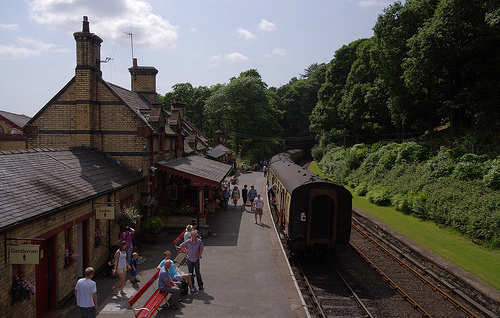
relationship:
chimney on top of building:
[66, 20, 128, 88] [46, 56, 227, 180]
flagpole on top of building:
[128, 30, 139, 67] [0, 15, 235, 317]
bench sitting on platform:
[127, 257, 184, 314] [73, 217, 216, 304]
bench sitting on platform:
[167, 225, 185, 251] [73, 217, 216, 304]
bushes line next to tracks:
[313, 141, 498, 240] [284, 208, 499, 316]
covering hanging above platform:
[165, 157, 235, 185] [159, 178, 213, 225]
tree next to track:
[201, 66, 289, 171] [355, 209, 481, 305]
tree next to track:
[155, 81, 226, 132] [355, 209, 481, 305]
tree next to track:
[270, 74, 320, 144] [355, 209, 481, 305]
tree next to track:
[308, 37, 372, 144] [355, 209, 481, 305]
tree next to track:
[397, 0, 497, 135] [355, 209, 481, 305]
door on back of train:
[310, 192, 336, 237] [268, 140, 376, 266]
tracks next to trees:
[359, 215, 462, 315] [295, 24, 499, 224]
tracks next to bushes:
[359, 215, 462, 315] [362, 152, 481, 210]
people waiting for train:
[228, 182, 269, 223] [273, 147, 355, 252]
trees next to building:
[218, 7, 495, 169] [66, 43, 237, 218]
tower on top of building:
[71, 14, 103, 76] [23, 74, 234, 237]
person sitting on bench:
[152, 260, 185, 309] [125, 253, 193, 316]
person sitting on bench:
[156, 249, 200, 295] [125, 253, 193, 316]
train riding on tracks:
[263, 143, 353, 255] [306, 208, 498, 314]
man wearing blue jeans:
[181, 229, 204, 294] [184, 257, 206, 295]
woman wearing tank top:
[112, 237, 129, 298] [117, 249, 127, 269]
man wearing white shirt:
[72, 276, 100, 309] [74, 275, 100, 308]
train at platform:
[265, 147, 355, 253] [61, 169, 308, 318]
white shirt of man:
[63, 272, 108, 303] [54, 255, 114, 306]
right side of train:
[253, 168, 297, 240] [245, 110, 381, 296]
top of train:
[268, 147, 340, 184] [265, 147, 355, 253]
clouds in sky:
[121, 6, 255, 70] [148, 6, 365, 78]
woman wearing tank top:
[110, 239, 132, 295] [113, 247, 128, 269]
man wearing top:
[155, 263, 191, 300] [151, 260, 196, 292]